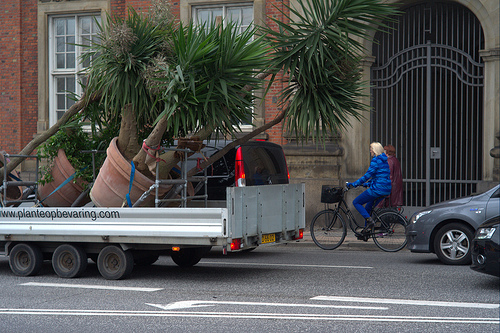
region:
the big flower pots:
[34, 140, 158, 201]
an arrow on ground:
[146, 297, 387, 317]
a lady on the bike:
[307, 139, 409, 252]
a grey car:
[404, 172, 499, 262]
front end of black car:
[466, 214, 499, 282]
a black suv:
[22, 134, 292, 269]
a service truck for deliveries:
[2, 182, 308, 282]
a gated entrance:
[367, 5, 484, 215]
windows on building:
[35, 0, 263, 140]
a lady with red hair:
[384, 142, 401, 239]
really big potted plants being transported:
[2, 0, 394, 208]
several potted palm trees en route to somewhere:
[1, 0, 398, 204]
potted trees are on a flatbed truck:
[0, 183, 308, 276]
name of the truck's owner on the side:
[1, 206, 122, 222]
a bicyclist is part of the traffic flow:
[308, 137, 413, 256]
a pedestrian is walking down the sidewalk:
[376, 140, 403, 237]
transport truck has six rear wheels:
[3, 240, 207, 281]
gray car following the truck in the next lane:
[402, 178, 498, 266]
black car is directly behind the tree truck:
[467, 208, 498, 279]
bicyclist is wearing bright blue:
[341, 137, 397, 228]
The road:
[0, 223, 495, 331]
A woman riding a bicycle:
[311, 140, 408, 248]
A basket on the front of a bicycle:
[317, 180, 344, 208]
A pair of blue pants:
[349, 187, 376, 227]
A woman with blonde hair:
[368, 139, 385, 157]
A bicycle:
[305, 180, 412, 257]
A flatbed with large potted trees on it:
[2, 2, 405, 268]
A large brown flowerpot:
[89, 132, 174, 212]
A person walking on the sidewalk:
[377, 142, 416, 233]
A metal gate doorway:
[369, 4, 491, 206]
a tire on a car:
[432, 221, 484, 275]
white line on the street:
[290, 291, 337, 322]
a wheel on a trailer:
[95, 246, 134, 283]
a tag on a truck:
[257, 227, 279, 243]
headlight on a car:
[475, 221, 497, 249]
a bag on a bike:
[320, 180, 351, 214]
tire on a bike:
[374, 210, 410, 259]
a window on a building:
[50, 41, 74, 90]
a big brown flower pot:
[88, 148, 148, 200]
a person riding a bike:
[337, 137, 398, 256]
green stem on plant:
[98, 65, 110, 110]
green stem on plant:
[105, 60, 130, 95]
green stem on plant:
[166, 56, 183, 81]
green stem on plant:
[218, 68, 228, 94]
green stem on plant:
[245, 43, 262, 55]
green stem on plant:
[224, 89, 249, 121]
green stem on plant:
[300, 44, 335, 79]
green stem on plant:
[329, 84, 362, 111]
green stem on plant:
[309, 114, 327, 134]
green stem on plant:
[299, 71, 327, 101]